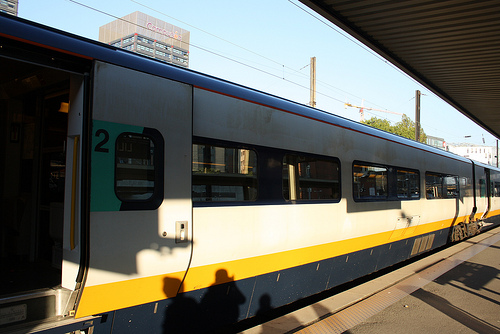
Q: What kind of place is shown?
A: It is a station.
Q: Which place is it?
A: It is a station.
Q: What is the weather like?
A: It is cloudless.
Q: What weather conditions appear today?
A: It is cloudless.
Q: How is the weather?
A: It is cloudless.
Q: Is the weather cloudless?
A: Yes, it is cloudless.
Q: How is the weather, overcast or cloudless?
A: It is cloudless.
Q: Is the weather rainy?
A: No, it is cloudless.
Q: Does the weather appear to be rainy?
A: No, it is cloudless.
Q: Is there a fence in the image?
A: No, there are no fences.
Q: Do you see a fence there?
A: No, there are no fences.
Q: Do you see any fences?
A: No, there are no fences.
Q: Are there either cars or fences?
A: No, there are no fences or cars.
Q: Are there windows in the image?
A: Yes, there is a window.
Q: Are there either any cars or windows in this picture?
A: Yes, there is a window.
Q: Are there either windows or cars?
A: Yes, there is a window.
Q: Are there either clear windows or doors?
A: Yes, there is a clear window.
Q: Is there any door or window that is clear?
A: Yes, the window is clear.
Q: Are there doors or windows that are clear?
A: Yes, the window is clear.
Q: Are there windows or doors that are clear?
A: Yes, the window is clear.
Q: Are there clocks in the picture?
A: No, there are no clocks.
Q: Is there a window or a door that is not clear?
A: No, there is a window but it is clear.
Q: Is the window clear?
A: Yes, the window is clear.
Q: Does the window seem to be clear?
A: Yes, the window is clear.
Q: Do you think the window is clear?
A: Yes, the window is clear.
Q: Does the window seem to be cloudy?
A: No, the window is clear.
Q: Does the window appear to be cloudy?
A: No, the window is clear.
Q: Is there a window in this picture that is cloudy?
A: No, there is a window but it is clear.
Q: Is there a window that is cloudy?
A: No, there is a window but it is clear.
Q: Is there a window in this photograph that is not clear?
A: No, there is a window but it is clear.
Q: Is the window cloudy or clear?
A: The window is clear.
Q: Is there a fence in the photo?
A: No, there are no fences.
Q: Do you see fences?
A: No, there are no fences.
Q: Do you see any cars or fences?
A: No, there are no fences or cars.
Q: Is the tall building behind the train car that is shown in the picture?
A: Yes, the building is behind the train car.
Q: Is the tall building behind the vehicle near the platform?
A: Yes, the building is behind the train car.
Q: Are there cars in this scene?
A: No, there are no cars.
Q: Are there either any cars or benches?
A: No, there are no cars or benches.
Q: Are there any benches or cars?
A: No, there are no cars or benches.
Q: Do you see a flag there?
A: No, there are no flags.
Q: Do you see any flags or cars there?
A: No, there are no flags or cars.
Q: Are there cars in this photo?
A: No, there are no cars.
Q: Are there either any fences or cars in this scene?
A: No, there are no cars or fences.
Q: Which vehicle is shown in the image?
A: The vehicle is a train car.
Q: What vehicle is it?
A: The vehicle is a train car.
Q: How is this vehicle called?
A: That is a train car.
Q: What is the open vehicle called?
A: The vehicle is a train car.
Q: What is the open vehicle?
A: The vehicle is a train car.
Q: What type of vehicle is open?
A: The vehicle is a train car.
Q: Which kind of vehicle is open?
A: The vehicle is a train car.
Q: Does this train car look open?
A: Yes, the train car is open.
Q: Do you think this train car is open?
A: Yes, the train car is open.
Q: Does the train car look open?
A: Yes, the train car is open.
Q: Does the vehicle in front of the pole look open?
A: Yes, the train car is open.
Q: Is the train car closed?
A: No, the train car is open.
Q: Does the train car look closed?
A: No, the train car is open.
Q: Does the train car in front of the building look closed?
A: No, the train car is open.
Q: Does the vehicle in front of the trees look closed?
A: No, the train car is open.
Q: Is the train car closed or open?
A: The train car is open.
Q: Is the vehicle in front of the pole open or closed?
A: The train car is open.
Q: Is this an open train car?
A: Yes, this is an open train car.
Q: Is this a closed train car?
A: No, this is an open train car.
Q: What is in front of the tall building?
A: The train car is in front of the building.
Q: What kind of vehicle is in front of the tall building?
A: The vehicle is a train car.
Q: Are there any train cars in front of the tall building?
A: Yes, there is a train car in front of the building.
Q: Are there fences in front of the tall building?
A: No, there is a train car in front of the building.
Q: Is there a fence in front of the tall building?
A: No, there is a train car in front of the building.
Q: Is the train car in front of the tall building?
A: Yes, the train car is in front of the building.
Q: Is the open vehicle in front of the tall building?
A: Yes, the train car is in front of the building.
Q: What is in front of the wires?
A: The train car is in front of the wires.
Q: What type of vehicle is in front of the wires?
A: The vehicle is a train car.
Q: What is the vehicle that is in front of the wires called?
A: The vehicle is a train car.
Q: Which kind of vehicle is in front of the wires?
A: The vehicle is a train car.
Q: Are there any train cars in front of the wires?
A: Yes, there is a train car in front of the wires.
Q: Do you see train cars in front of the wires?
A: Yes, there is a train car in front of the wires.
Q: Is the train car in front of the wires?
A: Yes, the train car is in front of the wires.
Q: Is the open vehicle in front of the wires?
A: Yes, the train car is in front of the wires.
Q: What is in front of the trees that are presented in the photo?
A: The train car is in front of the trees.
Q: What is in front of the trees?
A: The train car is in front of the trees.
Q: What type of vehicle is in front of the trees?
A: The vehicle is a train car.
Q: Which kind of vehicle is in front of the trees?
A: The vehicle is a train car.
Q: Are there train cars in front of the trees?
A: Yes, there is a train car in front of the trees.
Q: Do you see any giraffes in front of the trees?
A: No, there is a train car in front of the trees.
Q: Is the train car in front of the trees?
A: Yes, the train car is in front of the trees.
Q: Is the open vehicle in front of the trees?
A: Yes, the train car is in front of the trees.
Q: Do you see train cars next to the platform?
A: Yes, there is a train car next to the platform.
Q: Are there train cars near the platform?
A: Yes, there is a train car near the platform.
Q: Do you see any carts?
A: No, there are no carts.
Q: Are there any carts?
A: No, there are no carts.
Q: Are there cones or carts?
A: No, there are no carts or cones.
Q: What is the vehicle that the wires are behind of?
A: The vehicle is a train car.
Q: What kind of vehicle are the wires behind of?
A: The wires are behind the train car.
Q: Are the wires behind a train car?
A: Yes, the wires are behind a train car.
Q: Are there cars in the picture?
A: No, there are no cars.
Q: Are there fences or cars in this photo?
A: No, there are no cars or fences.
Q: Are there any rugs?
A: No, there are no rugs.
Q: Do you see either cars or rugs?
A: No, there are no rugs or cars.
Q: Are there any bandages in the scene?
A: No, there are no bandages.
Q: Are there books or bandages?
A: No, there are no bandages or books.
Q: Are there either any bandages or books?
A: No, there are no bandages or books.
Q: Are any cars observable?
A: No, there are no cars.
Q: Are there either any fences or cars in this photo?
A: No, there are no cars or fences.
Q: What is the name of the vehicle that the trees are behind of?
A: The vehicle is a train car.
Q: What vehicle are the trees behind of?
A: The trees are behind the train car.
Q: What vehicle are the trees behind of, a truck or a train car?
A: The trees are behind a train car.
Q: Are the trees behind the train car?
A: Yes, the trees are behind the train car.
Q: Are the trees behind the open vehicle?
A: Yes, the trees are behind the train car.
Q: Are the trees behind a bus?
A: No, the trees are behind the train car.